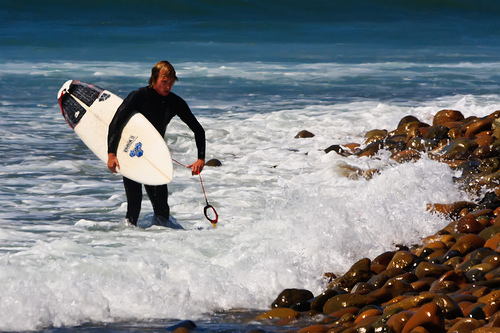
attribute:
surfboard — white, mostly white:
[58, 80, 175, 185]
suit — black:
[106, 88, 206, 226]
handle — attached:
[203, 205, 219, 225]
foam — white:
[0, 92, 497, 332]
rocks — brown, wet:
[257, 110, 500, 333]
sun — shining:
[0, 2, 499, 332]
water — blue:
[2, 2, 496, 333]